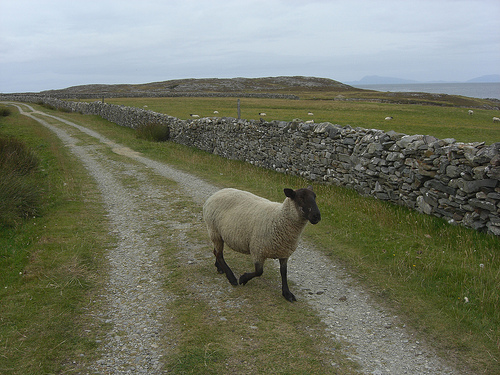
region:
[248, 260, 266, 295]
sheep has a black foot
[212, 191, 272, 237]
the sheep has white fur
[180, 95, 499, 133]
a bunch of sheep in the background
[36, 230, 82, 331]
green grass on the ground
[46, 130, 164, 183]
a worn trail on the road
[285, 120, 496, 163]
a wall made of rocks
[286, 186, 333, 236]
the sheep has a black face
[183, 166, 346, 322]
the sheep seems to be running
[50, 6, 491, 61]
grey skies in the background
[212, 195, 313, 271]
the sheep fur looks very soft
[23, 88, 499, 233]
a wall made of stones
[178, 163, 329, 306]
a lonely sheep on the path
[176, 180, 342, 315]
the sheep is off white and brown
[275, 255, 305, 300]
the leg of a sheep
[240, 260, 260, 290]
the leg of a sheep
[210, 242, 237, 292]
the leg of a sheep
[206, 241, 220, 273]
the leg of a sheep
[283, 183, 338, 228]
the head of a sheep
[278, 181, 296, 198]
the ear of a sheep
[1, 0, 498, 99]
a clear blue sky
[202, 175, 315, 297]
A lone sheep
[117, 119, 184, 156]
A small bush near the wall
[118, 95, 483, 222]
A stone wall near the camera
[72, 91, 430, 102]
A stone wall far in the distance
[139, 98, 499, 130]
A group of sheep in the pasture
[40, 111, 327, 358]
A dirt and stone road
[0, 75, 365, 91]
A rocky hill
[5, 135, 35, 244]
A group of bushes on the side of the road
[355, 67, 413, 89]
Mountains far in the distance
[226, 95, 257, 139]
a post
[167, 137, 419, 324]
a lone sheep on its own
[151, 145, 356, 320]
the sheep has white wool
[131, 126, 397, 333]
the sheep has a black face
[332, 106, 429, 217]
the wall is stone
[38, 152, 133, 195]
the grass is green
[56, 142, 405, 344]
the sheep is on the road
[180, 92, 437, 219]
there are sheep in the field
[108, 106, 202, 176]
a bush by the wall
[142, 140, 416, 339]
this sheep has escaped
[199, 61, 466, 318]
the hills are distant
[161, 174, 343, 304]
a sheep standing in the road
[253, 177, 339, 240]
a sheep with a black face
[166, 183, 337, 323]
a sheep with black feet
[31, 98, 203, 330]
a small dirt road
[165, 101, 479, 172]
a long rock wall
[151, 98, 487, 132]
several sheep in a field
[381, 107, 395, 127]
a sheep laying down in a field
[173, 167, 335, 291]
a black and white sheep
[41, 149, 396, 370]
a sheep crossing a road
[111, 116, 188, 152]
a bush next to a rock wall